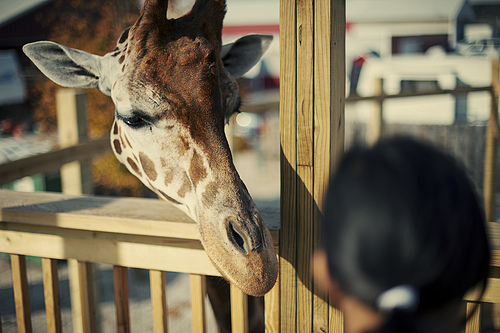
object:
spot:
[112, 121, 118, 135]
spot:
[112, 138, 122, 155]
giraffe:
[0, 0, 279, 298]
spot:
[119, 127, 135, 150]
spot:
[124, 156, 142, 178]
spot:
[175, 175, 193, 202]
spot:
[176, 132, 192, 158]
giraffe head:
[20, 0, 279, 299]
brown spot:
[160, 157, 177, 187]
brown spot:
[136, 151, 158, 182]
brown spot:
[189, 149, 208, 186]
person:
[304, 129, 499, 331]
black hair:
[319, 132, 493, 332]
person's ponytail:
[309, 130, 484, 332]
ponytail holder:
[375, 280, 418, 310]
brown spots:
[201, 180, 221, 209]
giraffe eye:
[122, 113, 155, 130]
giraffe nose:
[224, 217, 268, 254]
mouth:
[206, 253, 278, 297]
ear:
[22, 40, 101, 89]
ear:
[220, 33, 275, 78]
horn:
[184, 0, 228, 40]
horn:
[139, 0, 177, 36]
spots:
[155, 189, 183, 206]